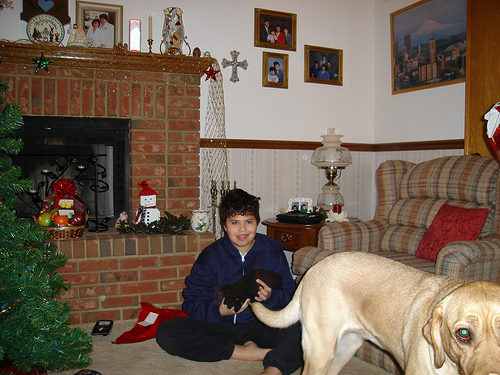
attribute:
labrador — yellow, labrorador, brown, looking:
[250, 248, 500, 375]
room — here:
[2, 3, 498, 369]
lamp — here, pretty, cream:
[321, 120, 349, 217]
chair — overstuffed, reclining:
[380, 161, 498, 273]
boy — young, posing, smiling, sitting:
[158, 186, 301, 373]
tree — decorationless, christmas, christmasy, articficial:
[0, 77, 96, 368]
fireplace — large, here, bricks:
[3, 42, 211, 331]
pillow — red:
[410, 196, 490, 261]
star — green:
[35, 51, 54, 75]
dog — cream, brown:
[422, 270, 497, 373]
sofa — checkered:
[306, 129, 500, 262]